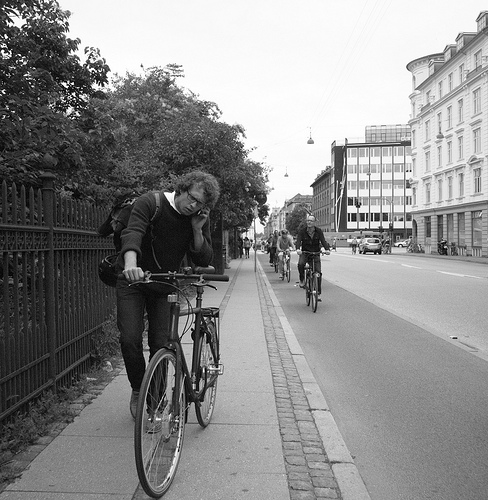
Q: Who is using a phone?
A: The closest man.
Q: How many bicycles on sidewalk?
A: One.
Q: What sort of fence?
A: Iron.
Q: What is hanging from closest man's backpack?
A: Helmet.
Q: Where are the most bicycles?
A: Street.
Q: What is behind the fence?
A: Trees.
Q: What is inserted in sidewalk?
A: Bricks.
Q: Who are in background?
A: Pedestrians.